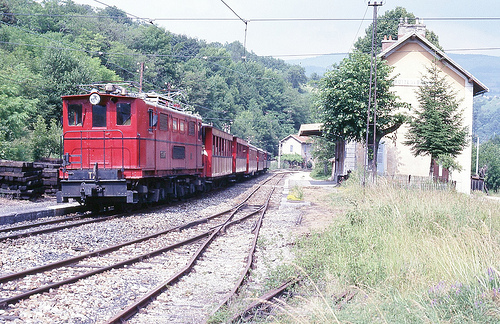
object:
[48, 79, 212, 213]
caboose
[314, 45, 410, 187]
trees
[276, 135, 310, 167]
building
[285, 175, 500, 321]
grass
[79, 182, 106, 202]
hook up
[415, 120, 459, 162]
ground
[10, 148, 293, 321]
railroad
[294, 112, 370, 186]
depot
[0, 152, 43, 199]
pallet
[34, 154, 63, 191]
pallet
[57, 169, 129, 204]
ram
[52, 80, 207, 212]
car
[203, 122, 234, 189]
car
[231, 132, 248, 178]
car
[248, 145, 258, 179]
car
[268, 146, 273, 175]
car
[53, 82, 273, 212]
train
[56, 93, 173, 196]
front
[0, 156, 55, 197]
railroad ties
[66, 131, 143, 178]
gate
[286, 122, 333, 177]
train station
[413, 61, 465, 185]
tree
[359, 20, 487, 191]
building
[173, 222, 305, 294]
tracks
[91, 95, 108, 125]
window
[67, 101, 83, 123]
window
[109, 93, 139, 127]
window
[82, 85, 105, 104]
light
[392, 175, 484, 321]
side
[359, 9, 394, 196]
pole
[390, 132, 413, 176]
side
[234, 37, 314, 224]
background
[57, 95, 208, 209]
line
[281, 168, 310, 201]
grass